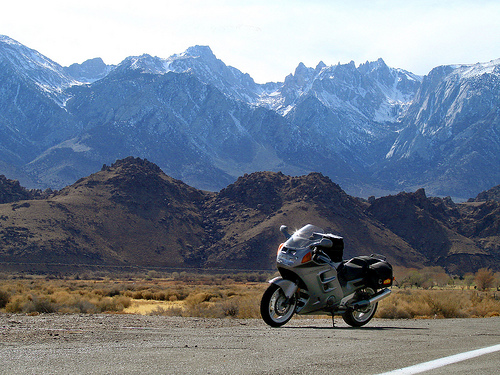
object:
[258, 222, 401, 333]
motorcycle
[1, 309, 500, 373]
road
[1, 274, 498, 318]
grass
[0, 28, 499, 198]
mountains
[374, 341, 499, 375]
line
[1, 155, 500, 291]
hills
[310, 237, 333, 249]
mirrors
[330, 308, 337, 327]
kickstand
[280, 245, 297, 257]
lights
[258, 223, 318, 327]
front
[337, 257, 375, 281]
seat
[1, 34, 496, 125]
snow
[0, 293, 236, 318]
shrubs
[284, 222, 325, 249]
windshield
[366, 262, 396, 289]
container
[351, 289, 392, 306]
pipe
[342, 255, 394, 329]
rear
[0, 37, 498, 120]
tops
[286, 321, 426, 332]
shadow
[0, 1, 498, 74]
sky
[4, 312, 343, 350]
side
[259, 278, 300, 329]
wheels